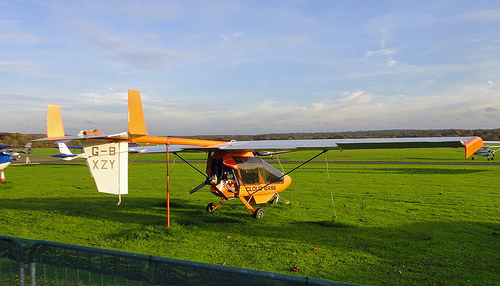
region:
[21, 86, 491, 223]
Yellow plane on the grass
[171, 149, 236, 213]
Propeller in front of plane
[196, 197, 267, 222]
Front wheels of plane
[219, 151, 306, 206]
Cockpit of plane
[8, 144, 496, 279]
Field is covered with green grass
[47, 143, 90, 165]
Blue and white plane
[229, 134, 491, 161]
Wing of plane has yellow end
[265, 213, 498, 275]
Shadow of plane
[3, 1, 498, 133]
Blue sky with white clouds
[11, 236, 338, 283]
Fence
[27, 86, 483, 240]
an airplane of odd design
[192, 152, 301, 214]
a yellow cabin on a plane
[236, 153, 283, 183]
windshield and window on the cabin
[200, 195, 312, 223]
Three point landing gear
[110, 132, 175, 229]
support poles for extended tail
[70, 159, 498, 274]
a grass parking area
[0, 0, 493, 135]
a partly cloudy sky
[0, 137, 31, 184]
a blue and white plane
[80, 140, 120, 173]
call letters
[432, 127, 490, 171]
yellow tip of the wing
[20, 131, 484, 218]
Orange mini helicopter.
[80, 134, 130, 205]
Plan tagging reads G-B XZY.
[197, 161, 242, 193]
Rear-end motor on helicopter.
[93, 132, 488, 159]
Silver and orange helicopter wings.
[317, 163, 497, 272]
Green grassy airplane field.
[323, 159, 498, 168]
Black topped airplane field.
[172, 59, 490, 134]
Sunny sky with light clouds.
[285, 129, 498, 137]
Mountain ranges in the background.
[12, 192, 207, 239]
Shadow of helicopter on grass.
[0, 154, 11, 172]
Blue and white nose of plane.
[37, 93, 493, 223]
small yellow and grey plane on grass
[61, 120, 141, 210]
plane identification on hanging flap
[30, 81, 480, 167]
wings extended over body of plane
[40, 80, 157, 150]
perpendicular panels on back of plane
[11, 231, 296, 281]
fencing near the back of plane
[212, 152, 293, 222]
dark tinted windows on plane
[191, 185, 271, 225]
splayed metal supports for wheels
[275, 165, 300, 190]
rounded nose of plane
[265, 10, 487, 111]
blue sky with long lines of airy clouds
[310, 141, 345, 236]
wire attaching plane to ground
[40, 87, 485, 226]
yellow plane parked on green grass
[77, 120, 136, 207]
white wing with black G-B XZY letters on it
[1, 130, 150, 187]
blue and white planes in distance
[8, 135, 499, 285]
bright green grassy airfield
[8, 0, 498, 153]
bright clear blue daytime sky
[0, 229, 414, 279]
silver metal railing next to airfield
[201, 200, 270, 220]
two black front wheels visible on yellow plabe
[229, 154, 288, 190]
large glass windows on yellow plane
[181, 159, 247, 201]
front propeller on yellow plane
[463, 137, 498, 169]
white plane parked on field in background